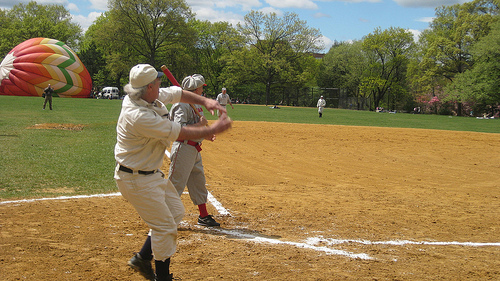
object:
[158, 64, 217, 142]
bat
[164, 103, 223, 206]
uniforms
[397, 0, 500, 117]
tree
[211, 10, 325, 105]
tree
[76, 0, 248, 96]
tree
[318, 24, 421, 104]
tree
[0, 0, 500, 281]
park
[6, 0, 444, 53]
sky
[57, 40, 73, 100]
stripe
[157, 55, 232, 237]
baseball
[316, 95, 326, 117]
person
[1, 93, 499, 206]
grass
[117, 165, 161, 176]
belt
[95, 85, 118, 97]
van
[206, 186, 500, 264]
chalk line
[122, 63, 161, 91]
white hat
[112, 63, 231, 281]
man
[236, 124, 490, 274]
dirt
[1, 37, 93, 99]
air balloon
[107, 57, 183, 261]
umpire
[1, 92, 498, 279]
ground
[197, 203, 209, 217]
red sock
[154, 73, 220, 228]
batter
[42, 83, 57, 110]
player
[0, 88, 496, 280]
field